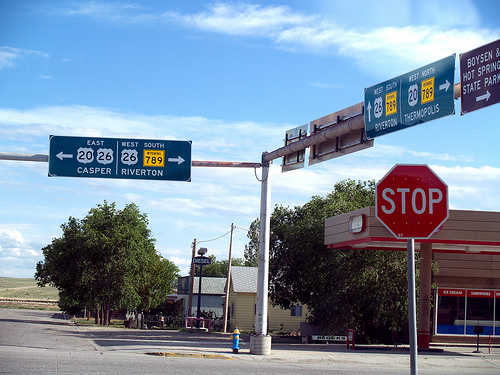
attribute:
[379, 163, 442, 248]
sign — red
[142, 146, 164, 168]
sign — yellow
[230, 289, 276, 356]
fire hydrant — two colors, blue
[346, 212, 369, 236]
sign — blurry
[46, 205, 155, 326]
trees — green, large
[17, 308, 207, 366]
road — gray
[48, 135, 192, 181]
sign — green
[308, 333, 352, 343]
sign — diesel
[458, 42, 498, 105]
sign — purple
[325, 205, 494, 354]
store — behind stop sign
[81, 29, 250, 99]
sky — blue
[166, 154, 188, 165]
arrow — white